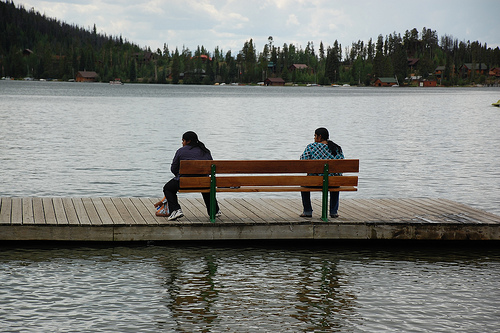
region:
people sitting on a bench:
[158, 128, 358, 223]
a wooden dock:
[8, 194, 497, 235]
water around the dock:
[14, 252, 463, 332]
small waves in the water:
[63, 154, 147, 181]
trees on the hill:
[38, 32, 483, 65]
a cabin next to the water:
[367, 74, 399, 88]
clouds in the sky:
[112, 5, 339, 33]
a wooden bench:
[170, 155, 360, 193]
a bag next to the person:
[155, 195, 174, 216]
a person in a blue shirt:
[293, 125, 355, 210]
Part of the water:
[176, 290, 232, 312]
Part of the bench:
[193, 165, 203, 169]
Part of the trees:
[10, 59, 22, 65]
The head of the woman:
[180, 130, 205, 148]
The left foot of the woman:
[164, 205, 187, 220]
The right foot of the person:
[327, 207, 343, 219]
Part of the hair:
[320, 128, 325, 133]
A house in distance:
[73, 69, 100, 83]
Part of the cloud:
[203, 7, 217, 17]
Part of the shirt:
[318, 149, 327, 156]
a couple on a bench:
[163, 122, 358, 221]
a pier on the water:
[3, 191, 489, 250]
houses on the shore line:
[210, 79, 480, 86]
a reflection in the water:
[168, 249, 360, 324]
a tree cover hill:
[0, 0, 135, 75]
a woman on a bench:
[155, 128, 223, 229]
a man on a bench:
[289, 127, 357, 221]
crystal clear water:
[28, 96, 465, 123]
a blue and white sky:
[138, 0, 418, 33]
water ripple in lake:
[41, 288, 67, 308]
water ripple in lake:
[184, 261, 206, 286]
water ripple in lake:
[263, 264, 298, 293]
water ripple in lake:
[298, 288, 325, 315]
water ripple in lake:
[339, 282, 367, 301]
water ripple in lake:
[404, 274, 430, 299]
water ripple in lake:
[424, 298, 455, 323]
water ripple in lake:
[371, 306, 396, 325]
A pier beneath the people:
[0, 198, 495, 240]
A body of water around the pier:
[1, 80, 498, 332]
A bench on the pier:
[177, 158, 361, 218]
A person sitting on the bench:
[157, 131, 221, 218]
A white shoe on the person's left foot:
[168, 207, 185, 219]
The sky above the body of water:
[11, 1, 498, 52]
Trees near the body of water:
[4, 1, 499, 86]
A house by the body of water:
[76, 69, 97, 81]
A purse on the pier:
[154, 195, 169, 217]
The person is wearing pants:
[299, 182, 342, 217]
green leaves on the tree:
[296, 52, 321, 77]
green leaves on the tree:
[267, 56, 281, 76]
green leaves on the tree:
[418, 28, 442, 50]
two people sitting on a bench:
[156, 126, 346, 218]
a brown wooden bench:
[172, 152, 364, 201]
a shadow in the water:
[161, 240, 363, 332]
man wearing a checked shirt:
[293, 125, 349, 221]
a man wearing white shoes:
[163, 129, 225, 224]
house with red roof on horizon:
[196, 49, 213, 66]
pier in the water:
[1, 189, 498, 245]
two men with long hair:
[161, 123, 348, 216]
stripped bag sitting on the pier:
[151, 195, 172, 222]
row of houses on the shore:
[3, 43, 498, 89]